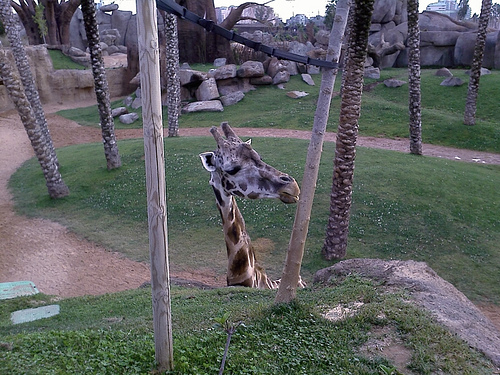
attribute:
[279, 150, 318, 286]
tree trunk — small, gray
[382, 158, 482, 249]
green grass — on a lawn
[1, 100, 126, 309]
path — brown dirt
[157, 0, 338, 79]
black strap — on a tree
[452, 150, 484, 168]
water puddle — in the dirt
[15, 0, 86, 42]
tree — large, brown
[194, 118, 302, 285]
tall giraffe — in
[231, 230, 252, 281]
brown spots — on giraffe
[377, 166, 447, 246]
green grass — in field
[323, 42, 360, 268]
trunk — of tall tree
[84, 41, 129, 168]
trunk — of tall tree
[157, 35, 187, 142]
trunk — of tall tree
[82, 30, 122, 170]
trunk — of tall tree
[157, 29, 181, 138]
trunk — of tall tree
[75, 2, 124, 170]
trunk — of tall tree